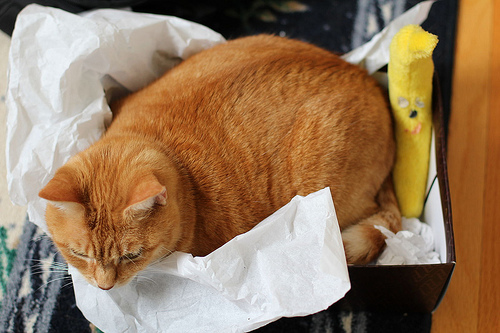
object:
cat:
[38, 33, 403, 290]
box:
[323, 73, 457, 313]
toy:
[387, 23, 438, 218]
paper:
[5, 2, 443, 328]